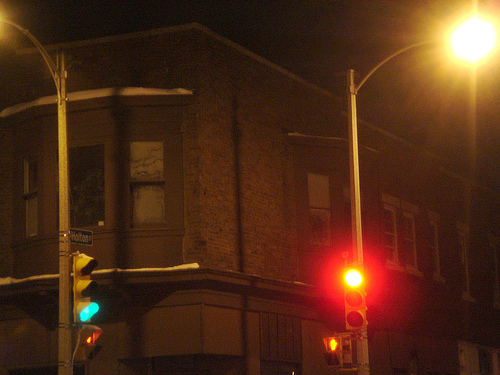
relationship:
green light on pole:
[76, 302, 100, 322] [55, 106, 71, 374]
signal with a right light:
[342, 251, 370, 332] [343, 268, 364, 287]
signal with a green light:
[71, 250, 101, 326] [76, 302, 100, 322]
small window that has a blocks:
[257, 312, 304, 374] [259, 313, 302, 363]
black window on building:
[70, 145, 105, 226] [1, 23, 498, 374]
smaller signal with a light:
[323, 334, 344, 357] [329, 338, 340, 354]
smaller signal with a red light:
[323, 334, 344, 357] [329, 338, 340, 354]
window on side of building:
[21, 155, 43, 239] [1, 23, 498, 374]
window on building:
[21, 155, 43, 239] [1, 23, 498, 374]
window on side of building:
[305, 169, 333, 245] [1, 23, 498, 374]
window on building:
[381, 205, 399, 268] [1, 23, 498, 374]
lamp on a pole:
[431, 5, 499, 76] [344, 68, 372, 374]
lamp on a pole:
[1, 11, 21, 40] [55, 106, 71, 374]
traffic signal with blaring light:
[342, 251, 370, 332] [317, 250, 393, 309]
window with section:
[21, 155, 43, 239] [25, 197, 43, 236]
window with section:
[21, 155, 43, 239] [22, 160, 40, 193]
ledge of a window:
[130, 222, 166, 232] [128, 137, 169, 226]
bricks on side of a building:
[187, 105, 287, 257] [1, 23, 498, 374]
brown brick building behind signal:
[1, 23, 498, 374] [342, 251, 370, 332]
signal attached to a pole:
[342, 251, 370, 332] [344, 68, 372, 374]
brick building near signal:
[1, 23, 498, 374] [342, 251, 370, 332]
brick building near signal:
[1, 23, 498, 374] [71, 250, 101, 326]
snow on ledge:
[1, 85, 194, 120] [1, 95, 192, 127]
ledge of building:
[1, 95, 192, 127] [1, 23, 498, 374]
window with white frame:
[381, 205, 399, 268] [383, 206, 397, 268]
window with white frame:
[401, 212, 419, 274] [402, 211, 417, 271]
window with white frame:
[428, 220, 442, 284] [426, 218, 439, 276]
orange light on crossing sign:
[328, 338, 339, 353] [323, 334, 344, 357]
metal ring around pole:
[57, 229, 70, 245] [55, 106, 71, 374]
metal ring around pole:
[56, 248, 72, 259] [55, 106, 71, 374]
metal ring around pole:
[55, 320, 71, 333] [55, 106, 71, 374]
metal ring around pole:
[56, 356, 72, 368] [55, 106, 71, 374]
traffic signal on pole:
[71, 250, 101, 326] [55, 106, 71, 374]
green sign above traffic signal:
[69, 227, 96, 246] [71, 250, 101, 326]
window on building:
[128, 137, 169, 226] [1, 23, 498, 374]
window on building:
[305, 169, 333, 245] [1, 23, 498, 374]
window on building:
[401, 212, 419, 274] [1, 23, 498, 374]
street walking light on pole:
[323, 334, 344, 357] [344, 68, 372, 374]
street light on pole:
[431, 5, 499, 76] [344, 68, 372, 374]